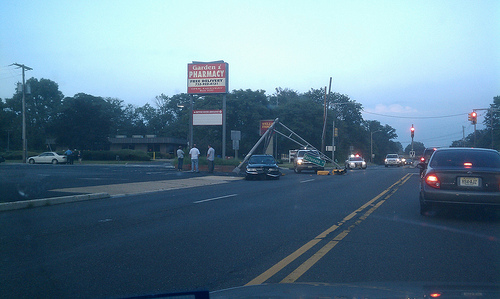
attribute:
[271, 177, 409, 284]
lines — yelllow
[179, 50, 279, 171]
signs — red, white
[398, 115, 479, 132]
lights — red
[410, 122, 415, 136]
traffic light — red traffic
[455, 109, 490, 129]
lights — red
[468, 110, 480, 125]
traffic light — red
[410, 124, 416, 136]
stop light — Two stop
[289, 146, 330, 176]
car — police, white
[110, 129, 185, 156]
building — low brown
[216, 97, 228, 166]
pole — metal 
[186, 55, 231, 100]
sign —  red , white 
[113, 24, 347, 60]
sky — bright light-blue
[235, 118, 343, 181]
pole — fallen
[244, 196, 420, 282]
surface — paved 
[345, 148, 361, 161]
lights —  red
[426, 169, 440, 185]
lights — red rear 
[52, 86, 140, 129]
trees — under 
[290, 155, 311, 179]
light — white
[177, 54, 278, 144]
sign — behind